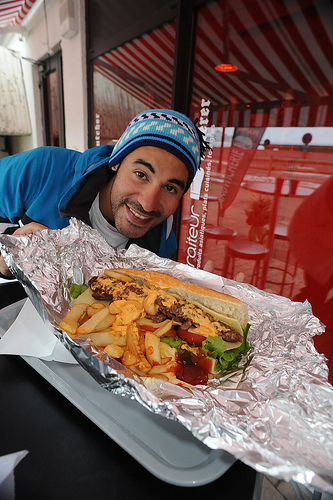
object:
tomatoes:
[143, 322, 207, 347]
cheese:
[98, 277, 228, 337]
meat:
[88, 274, 243, 344]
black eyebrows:
[132, 158, 155, 174]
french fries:
[60, 298, 194, 389]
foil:
[13, 234, 119, 265]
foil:
[253, 305, 315, 469]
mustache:
[125, 198, 161, 219]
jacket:
[0, 145, 176, 258]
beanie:
[108, 107, 200, 195]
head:
[111, 107, 201, 237]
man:
[0, 107, 200, 280]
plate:
[260, 325, 286, 394]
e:
[189, 227, 199, 239]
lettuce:
[70, 281, 254, 371]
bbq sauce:
[174, 344, 212, 385]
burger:
[59, 267, 251, 388]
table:
[23, 401, 128, 497]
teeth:
[129, 208, 149, 220]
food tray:
[0, 293, 241, 487]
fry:
[144, 328, 161, 365]